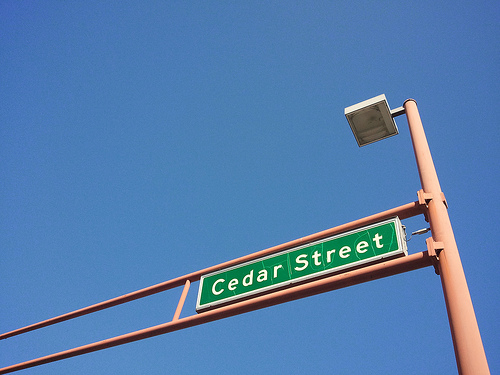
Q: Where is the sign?
A: In Between two poles.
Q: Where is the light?
A: Above the sign.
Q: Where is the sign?
A: Below the light.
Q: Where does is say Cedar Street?
A: On the sign.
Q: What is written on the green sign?
A: Cedar Street.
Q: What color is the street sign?
A: Green.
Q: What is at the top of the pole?
A: A light.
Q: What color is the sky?
A: Blue.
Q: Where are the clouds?
A: Not visible.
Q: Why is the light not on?
A: It is daytime.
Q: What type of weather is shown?
A: Clear and sunny.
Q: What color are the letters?
A: White.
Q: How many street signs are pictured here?
A: One.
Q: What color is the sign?
A: Green.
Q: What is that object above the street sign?
A: A street lamp.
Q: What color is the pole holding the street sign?
A: Orange.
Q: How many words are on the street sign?
A: 2.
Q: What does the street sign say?
A: Cedar Street.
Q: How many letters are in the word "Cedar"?
A: 5.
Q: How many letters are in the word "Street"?
A: 6.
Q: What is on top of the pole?
A: A street light.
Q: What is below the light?
A: A street sign.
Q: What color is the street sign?
A: Green.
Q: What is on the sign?
A: Writing.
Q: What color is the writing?
A: White.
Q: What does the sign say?
A: Cedar Street.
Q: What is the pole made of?
A: Metal.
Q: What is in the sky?
A: Nothing.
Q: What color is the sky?
A: Blue.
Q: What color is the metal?
A: Red.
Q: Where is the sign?
A: Cedar Street.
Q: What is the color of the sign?
A: Green.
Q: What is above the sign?
A: A light.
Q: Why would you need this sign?
A: To find directions.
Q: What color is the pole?
A: Brown.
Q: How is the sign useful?
A: To find an address.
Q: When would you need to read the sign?
A: To find an address.